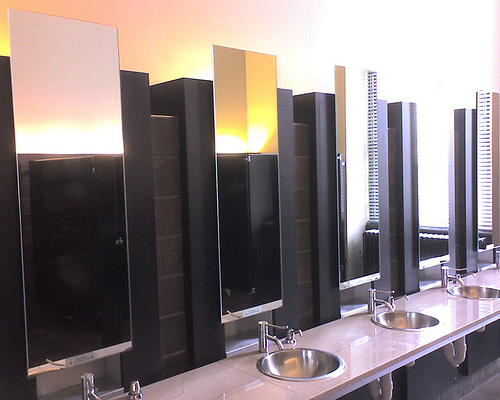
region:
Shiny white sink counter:
[355, 336, 395, 372]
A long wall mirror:
[5, 8, 138, 370]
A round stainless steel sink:
[265, 347, 345, 384]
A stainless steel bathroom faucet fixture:
[364, 286, 398, 316]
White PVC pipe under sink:
[439, 339, 470, 368]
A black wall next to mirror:
[182, 92, 216, 367]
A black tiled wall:
[155, 110, 191, 367]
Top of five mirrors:
[7, 7, 498, 200]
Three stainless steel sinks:
[253, 274, 498, 390]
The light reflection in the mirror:
[207, 112, 272, 156]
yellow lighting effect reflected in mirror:
[189, 22, 305, 172]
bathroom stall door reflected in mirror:
[10, 129, 161, 351]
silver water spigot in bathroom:
[247, 316, 304, 358]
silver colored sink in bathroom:
[259, 341, 341, 384]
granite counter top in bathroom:
[180, 361, 267, 398]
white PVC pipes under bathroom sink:
[445, 331, 490, 384]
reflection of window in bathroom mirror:
[335, 66, 386, 290]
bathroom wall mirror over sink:
[7, 2, 160, 379]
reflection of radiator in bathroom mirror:
[360, 222, 499, 269]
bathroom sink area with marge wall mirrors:
[2, 37, 498, 397]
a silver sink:
[257, 347, 345, 385]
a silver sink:
[373, 304, 444, 336]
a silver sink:
[449, 283, 496, 299]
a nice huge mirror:
[6, 5, 141, 372]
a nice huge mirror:
[209, 38, 286, 320]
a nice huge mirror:
[332, 63, 382, 288]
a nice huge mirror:
[410, 47, 453, 274]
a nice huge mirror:
[471, 67, 499, 256]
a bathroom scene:
[1, 0, 498, 398]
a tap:
[251, 317, 303, 352]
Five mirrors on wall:
[24, 41, 497, 312]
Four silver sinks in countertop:
[63, 265, 497, 386]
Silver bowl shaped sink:
[250, 319, 374, 394]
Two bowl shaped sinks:
[239, 273, 468, 398]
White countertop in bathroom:
[127, 289, 479, 396]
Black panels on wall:
[127, 99, 219, 368]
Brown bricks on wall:
[150, 114, 192, 374]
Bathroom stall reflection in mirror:
[31, 156, 156, 342]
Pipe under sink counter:
[367, 363, 409, 398]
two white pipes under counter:
[369, 325, 484, 398]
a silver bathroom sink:
[245, 307, 354, 389]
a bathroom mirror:
[199, 33, 301, 340]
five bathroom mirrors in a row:
[4, 5, 496, 274]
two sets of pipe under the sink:
[362, 324, 492, 398]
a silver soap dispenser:
[280, 320, 309, 350]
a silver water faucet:
[254, 318, 286, 359]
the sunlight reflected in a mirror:
[409, 63, 454, 230]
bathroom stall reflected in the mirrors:
[19, 143, 296, 355]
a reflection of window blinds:
[360, 64, 389, 246]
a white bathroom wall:
[161, 0, 498, 37]